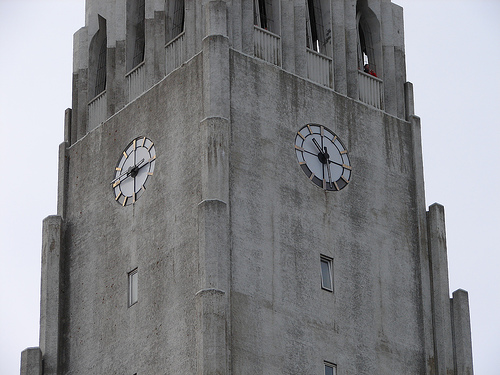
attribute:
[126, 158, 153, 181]
metal hand — black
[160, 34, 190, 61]
railing — concrete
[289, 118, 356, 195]
clock — modern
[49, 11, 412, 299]
building — large, grey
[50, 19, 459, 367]
tower — large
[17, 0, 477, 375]
building — large, concrete, grey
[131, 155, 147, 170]
hand — metal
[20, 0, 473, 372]
large building — grey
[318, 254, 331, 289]
window — rectangular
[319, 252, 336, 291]
window — rectangular 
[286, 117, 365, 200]
clock — mostly white, blackened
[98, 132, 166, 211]
clock — mostly white, blackened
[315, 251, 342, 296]
window — small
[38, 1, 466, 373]
tower — grey, concrete, stained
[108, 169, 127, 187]
hand — metal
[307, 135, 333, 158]
hand — metal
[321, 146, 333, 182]
hand — metal, black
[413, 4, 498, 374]
sky — cloudy, blue-grey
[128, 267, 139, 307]
window — rectangular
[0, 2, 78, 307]
sky — grey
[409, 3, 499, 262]
sky — grey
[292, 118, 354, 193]
clock face — modern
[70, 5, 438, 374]
building — grey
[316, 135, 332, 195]
hand — metal